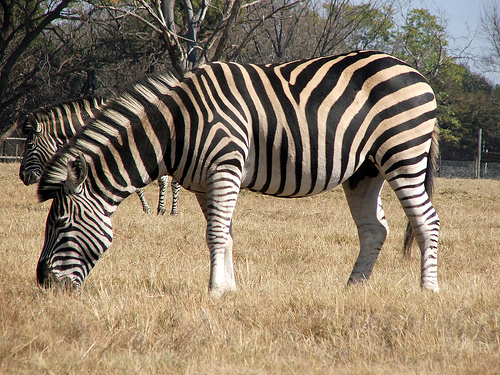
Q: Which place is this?
A: It is a pasture.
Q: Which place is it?
A: It is a pasture.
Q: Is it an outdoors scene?
A: Yes, it is outdoors.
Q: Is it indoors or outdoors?
A: It is outdoors.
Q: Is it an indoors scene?
A: No, it is outdoors.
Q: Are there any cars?
A: No, there are no cars.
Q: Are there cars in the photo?
A: No, there are no cars.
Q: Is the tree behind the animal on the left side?
A: Yes, the tree is behind the animal.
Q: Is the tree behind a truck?
A: No, the tree is behind the animal.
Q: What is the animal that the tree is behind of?
A: The animal is a zebra.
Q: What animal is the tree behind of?
A: The tree is behind the zebra.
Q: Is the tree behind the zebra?
A: Yes, the tree is behind the zebra.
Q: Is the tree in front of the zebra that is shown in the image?
A: No, the tree is behind the zebra.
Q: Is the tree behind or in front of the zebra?
A: The tree is behind the zebra.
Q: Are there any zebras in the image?
A: Yes, there is a zebra.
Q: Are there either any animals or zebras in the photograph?
A: Yes, there is a zebra.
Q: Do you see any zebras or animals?
A: Yes, there is a zebra.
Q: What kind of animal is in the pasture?
A: The animal is a zebra.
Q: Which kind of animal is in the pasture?
A: The animal is a zebra.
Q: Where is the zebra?
A: The zebra is in the pasture.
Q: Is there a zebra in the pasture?
A: Yes, there is a zebra in the pasture.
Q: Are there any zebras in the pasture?
A: Yes, there is a zebra in the pasture.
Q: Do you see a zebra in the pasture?
A: Yes, there is a zebra in the pasture.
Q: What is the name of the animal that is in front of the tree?
A: The animal is a zebra.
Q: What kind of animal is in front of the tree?
A: The animal is a zebra.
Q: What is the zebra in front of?
A: The zebra is in front of the tree.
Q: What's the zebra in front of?
A: The zebra is in front of the tree.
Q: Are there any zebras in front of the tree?
A: Yes, there is a zebra in front of the tree.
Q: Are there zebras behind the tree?
A: No, the zebra is in front of the tree.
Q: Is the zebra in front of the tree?
A: Yes, the zebra is in front of the tree.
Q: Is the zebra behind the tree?
A: No, the zebra is in front of the tree.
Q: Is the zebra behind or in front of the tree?
A: The zebra is in front of the tree.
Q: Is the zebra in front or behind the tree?
A: The zebra is in front of the tree.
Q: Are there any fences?
A: Yes, there is a fence.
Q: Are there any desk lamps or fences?
A: Yes, there is a fence.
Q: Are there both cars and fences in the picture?
A: No, there is a fence but no cars.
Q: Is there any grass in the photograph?
A: Yes, there is grass.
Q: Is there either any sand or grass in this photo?
A: Yes, there is grass.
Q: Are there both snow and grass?
A: No, there is grass but no snow.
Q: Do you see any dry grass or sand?
A: Yes, there is dry grass.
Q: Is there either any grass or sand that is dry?
A: Yes, the grass is dry.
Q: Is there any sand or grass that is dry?
A: Yes, the grass is dry.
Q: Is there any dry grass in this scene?
A: Yes, there is dry grass.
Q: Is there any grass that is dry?
A: Yes, there is grass that is dry.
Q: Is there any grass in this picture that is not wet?
A: Yes, there is dry grass.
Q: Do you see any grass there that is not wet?
A: Yes, there is dry grass.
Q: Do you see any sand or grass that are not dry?
A: No, there is grass but it is dry.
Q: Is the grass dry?
A: Yes, the grass is dry.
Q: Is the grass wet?
A: No, the grass is dry.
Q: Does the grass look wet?
A: No, the grass is dry.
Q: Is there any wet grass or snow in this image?
A: No, there is grass but it is dry.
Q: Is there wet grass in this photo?
A: No, there is grass but it is dry.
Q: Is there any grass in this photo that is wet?
A: No, there is grass but it is dry.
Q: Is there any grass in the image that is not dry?
A: No, there is grass but it is dry.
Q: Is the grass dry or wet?
A: The grass is dry.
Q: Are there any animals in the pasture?
A: Yes, there is an animal in the pasture.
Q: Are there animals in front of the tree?
A: Yes, there is an animal in front of the tree.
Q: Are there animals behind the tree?
A: No, the animal is in front of the tree.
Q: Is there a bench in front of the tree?
A: No, there is an animal in front of the tree.